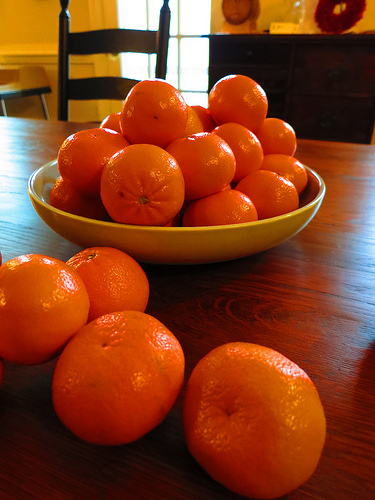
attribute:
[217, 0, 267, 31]
barrel — wooden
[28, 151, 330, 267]
bowl — is yellow, gold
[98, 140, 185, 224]
fruit — bright, orange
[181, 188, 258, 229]
fruit — orange, bright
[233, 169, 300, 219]
fruit — orange, bright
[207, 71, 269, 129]
fruit — orange, bright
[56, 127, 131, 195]
fruit — orange, bright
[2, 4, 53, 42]
wall — cream colored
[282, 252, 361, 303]
table top — wood, brown, dark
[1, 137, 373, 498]
table — wooden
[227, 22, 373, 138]
cabinet — is dark, is brown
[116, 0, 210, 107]
window — small paned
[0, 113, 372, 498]
chair — wooden chair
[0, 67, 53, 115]
table — side table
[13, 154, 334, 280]
bowl — is yellow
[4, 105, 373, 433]
table — is dark, is brown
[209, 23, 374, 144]
cabinet — is brown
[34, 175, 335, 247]
bowl — yellow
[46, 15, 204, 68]
chair — is brown, is wooden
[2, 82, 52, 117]
table — is metal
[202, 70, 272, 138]
fruit — bright, orange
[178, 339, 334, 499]
fruit — bright, orange